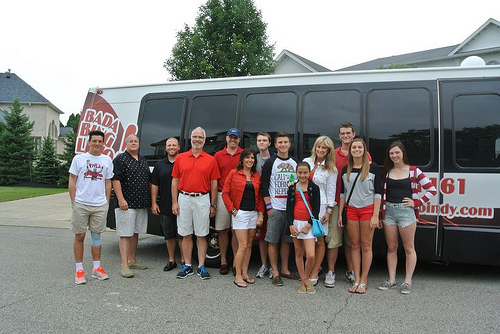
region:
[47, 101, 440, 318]
people are posing for picture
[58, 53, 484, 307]
a bus behind the people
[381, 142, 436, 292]
a woman wearing a black tank top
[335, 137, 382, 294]
a girl wearing a white shirt with black sleeves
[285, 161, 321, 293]
a little girl wearing a black jacket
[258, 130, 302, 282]
a man wearing a white t-shirt with black sleeves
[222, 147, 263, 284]
a woman wearing a red jacket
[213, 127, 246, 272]
a man wearing a red shirt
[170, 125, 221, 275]
a man wearing a red shirt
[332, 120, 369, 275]
a man wearing a red shirt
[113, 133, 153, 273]
a man wearing a black shirt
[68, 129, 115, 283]
a man wearing a white shirt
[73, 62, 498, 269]
a white bus with red writing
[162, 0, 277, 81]
a tall green tree behind bus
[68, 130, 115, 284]
a man wearing a white t-shirt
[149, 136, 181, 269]
a man wearing a black shirt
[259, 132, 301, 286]
a man wearing a white shirt with black sleeves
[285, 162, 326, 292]
a girl wearing a black jacket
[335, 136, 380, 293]
a woman wearing red shorts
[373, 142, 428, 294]
Girl wearing a black tank top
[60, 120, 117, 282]
Boy wearing a white shirt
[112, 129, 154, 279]
Man wearing a black shirt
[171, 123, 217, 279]
Man wearing tan shorts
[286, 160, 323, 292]
Girl wearing a black sweater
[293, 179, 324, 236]
Blue purse on girl's shoulder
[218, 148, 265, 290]
Woman wearing white shorts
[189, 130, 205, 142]
Eyeglasses on man's face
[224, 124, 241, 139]
Blue hat on man's head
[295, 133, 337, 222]
Woman wearing white jacket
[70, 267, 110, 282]
a pair of bright orange sneakers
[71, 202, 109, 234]
a pair of beige shorts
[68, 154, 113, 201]
a white t shirt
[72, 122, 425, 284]
a group of people posing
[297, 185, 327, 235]
a blue handbag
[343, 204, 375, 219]
a pair of red shorts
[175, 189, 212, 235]
a pair of beige shorts with a belt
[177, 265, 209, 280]
a pair of black sneakers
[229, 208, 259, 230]
a short white skirt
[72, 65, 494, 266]
a long white bus